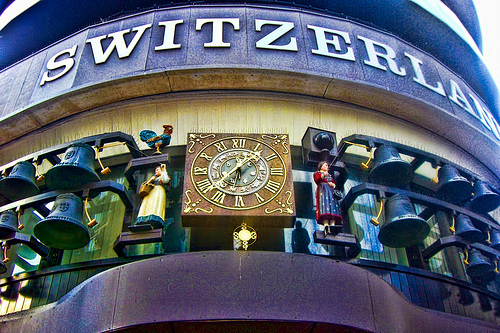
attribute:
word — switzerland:
[37, 15, 498, 142]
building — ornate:
[0, 1, 500, 333]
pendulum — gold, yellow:
[234, 223, 257, 249]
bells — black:
[1, 144, 95, 249]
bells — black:
[377, 144, 497, 275]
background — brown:
[185, 133, 294, 230]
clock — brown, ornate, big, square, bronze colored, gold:
[183, 133, 296, 227]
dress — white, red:
[314, 171, 343, 221]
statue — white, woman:
[313, 159, 342, 234]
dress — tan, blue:
[136, 170, 173, 226]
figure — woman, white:
[130, 165, 173, 227]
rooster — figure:
[137, 125, 173, 152]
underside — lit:
[0, 72, 498, 162]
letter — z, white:
[255, 20, 299, 53]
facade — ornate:
[2, 116, 499, 308]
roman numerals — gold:
[195, 139, 287, 208]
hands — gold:
[206, 150, 262, 194]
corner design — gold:
[188, 134, 218, 154]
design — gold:
[184, 191, 215, 217]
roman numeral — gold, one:
[254, 141, 263, 153]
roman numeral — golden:
[264, 152, 280, 162]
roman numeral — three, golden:
[270, 166, 286, 178]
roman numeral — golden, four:
[264, 178, 282, 194]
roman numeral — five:
[255, 191, 269, 204]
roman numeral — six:
[233, 193, 244, 210]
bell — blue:
[48, 143, 100, 194]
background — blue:
[0, 0, 500, 132]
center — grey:
[222, 157, 257, 186]